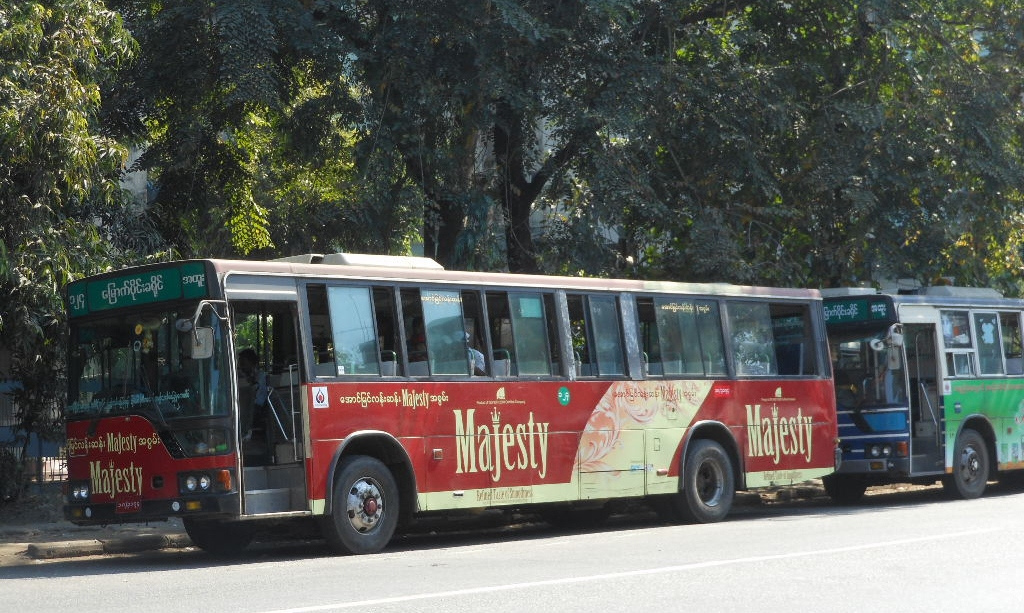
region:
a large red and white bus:
[46, 233, 869, 531]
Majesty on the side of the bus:
[449, 395, 563, 494]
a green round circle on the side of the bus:
[549, 385, 576, 405]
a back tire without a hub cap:
[680, 436, 748, 517]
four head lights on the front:
[60, 474, 219, 504]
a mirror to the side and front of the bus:
[179, 290, 243, 374]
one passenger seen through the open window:
[449, 316, 494, 378]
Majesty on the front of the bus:
[81, 458, 171, 501]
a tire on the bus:
[334, 448, 404, 550]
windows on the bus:
[313, 287, 820, 380]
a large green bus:
[824, 293, 1020, 480]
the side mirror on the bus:
[189, 300, 221, 359]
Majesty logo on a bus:
[425, 394, 556, 490]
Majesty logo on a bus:
[416, 389, 563, 488]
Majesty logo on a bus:
[428, 405, 562, 488]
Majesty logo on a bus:
[427, 382, 558, 501]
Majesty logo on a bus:
[431, 386, 561, 491]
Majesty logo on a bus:
[428, 388, 566, 490]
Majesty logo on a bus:
[425, 380, 559, 483]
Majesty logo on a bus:
[431, 382, 565, 493]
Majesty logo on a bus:
[431, 380, 561, 492]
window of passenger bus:
[418, 292, 472, 350]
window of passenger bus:
[476, 283, 559, 381]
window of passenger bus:
[593, 296, 645, 394]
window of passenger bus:
[625, 284, 728, 352]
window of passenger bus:
[728, 292, 804, 349]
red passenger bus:
[96, 239, 856, 499]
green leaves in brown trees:
[55, 31, 151, 104]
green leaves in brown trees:
[198, 78, 259, 121]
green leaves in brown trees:
[810, 10, 912, 77]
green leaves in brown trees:
[693, 171, 769, 232]